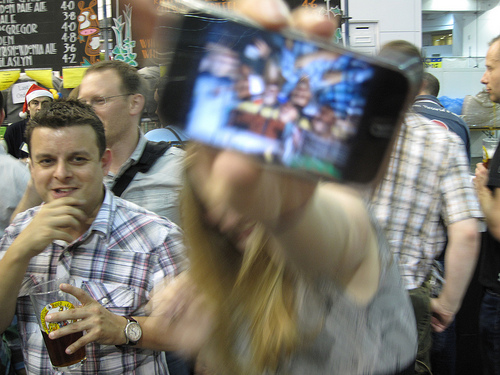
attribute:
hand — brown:
[29, 262, 181, 367]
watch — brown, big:
[114, 304, 146, 358]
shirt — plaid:
[397, 157, 426, 204]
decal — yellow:
[36, 297, 80, 340]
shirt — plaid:
[357, 108, 480, 289]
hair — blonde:
[161, 130, 357, 336]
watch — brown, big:
[121, 310, 148, 361]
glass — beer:
[477, 132, 499, 167]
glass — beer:
[23, 280, 97, 362]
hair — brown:
[34, 100, 94, 129]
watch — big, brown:
[122, 312, 142, 354]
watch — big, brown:
[117, 310, 147, 360]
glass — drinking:
[20, 274, 102, 372]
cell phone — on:
[156, 10, 411, 185]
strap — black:
[107, 140, 169, 195]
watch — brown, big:
[116, 311, 144, 353]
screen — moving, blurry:
[201, 25, 366, 179]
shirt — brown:
[32, 195, 218, 338]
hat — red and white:
[15, 73, 80, 114]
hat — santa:
[17, 82, 56, 122]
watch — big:
[119, 310, 145, 357]